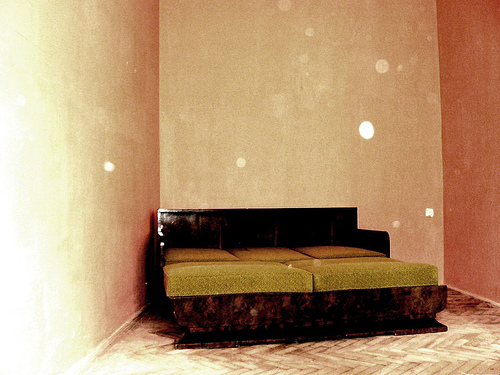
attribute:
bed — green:
[147, 192, 457, 338]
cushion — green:
[166, 261, 312, 293]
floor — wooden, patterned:
[408, 345, 465, 370]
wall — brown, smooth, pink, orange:
[187, 13, 257, 77]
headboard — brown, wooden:
[169, 201, 344, 239]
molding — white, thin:
[465, 289, 489, 309]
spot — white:
[374, 57, 392, 76]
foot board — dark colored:
[166, 284, 451, 352]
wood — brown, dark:
[161, 210, 219, 233]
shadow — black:
[137, 218, 153, 264]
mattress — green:
[168, 247, 425, 292]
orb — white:
[358, 121, 377, 142]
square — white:
[424, 205, 436, 220]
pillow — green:
[169, 244, 232, 262]